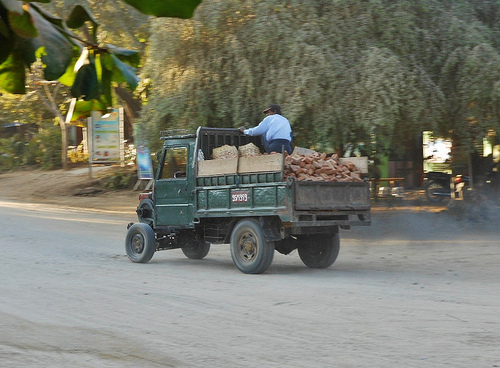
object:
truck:
[122, 118, 378, 277]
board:
[193, 152, 283, 175]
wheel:
[225, 214, 276, 277]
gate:
[291, 176, 376, 214]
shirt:
[240, 112, 295, 143]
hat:
[262, 102, 283, 114]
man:
[239, 102, 296, 157]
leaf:
[106, 51, 139, 95]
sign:
[85, 107, 125, 163]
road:
[2, 203, 498, 367]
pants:
[257, 136, 299, 156]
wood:
[290, 165, 301, 173]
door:
[148, 137, 196, 232]